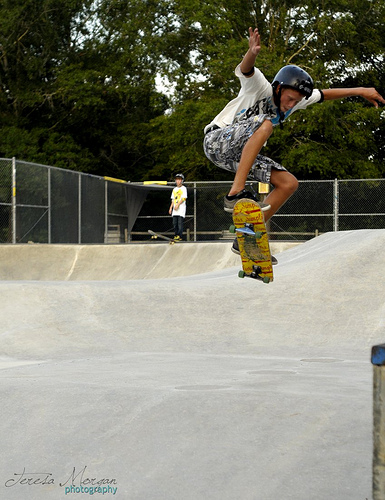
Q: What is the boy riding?
A: Skateboard.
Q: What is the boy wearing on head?
A: Helmet.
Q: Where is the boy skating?
A: Skate park.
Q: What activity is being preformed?
A: Skateboarding.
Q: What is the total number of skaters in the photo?
A: 2.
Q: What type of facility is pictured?
A: Skatepark.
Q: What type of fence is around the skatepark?
A: Chain link.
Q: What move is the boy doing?
A: Ollie.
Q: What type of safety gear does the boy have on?
A: A helmet.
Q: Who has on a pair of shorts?
A: The boy closest to the camera.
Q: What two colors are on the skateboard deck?
A: Red and yellow.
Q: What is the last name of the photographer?
A: Morgan.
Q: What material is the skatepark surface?
A: Concrete.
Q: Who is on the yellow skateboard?
A: A boy.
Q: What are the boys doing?
A: Skateboarding.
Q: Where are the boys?
A: At a skate park.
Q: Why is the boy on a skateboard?
A: He is skateboarding.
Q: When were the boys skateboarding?
A: During daylight hours.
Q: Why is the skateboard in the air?
A: The boy did a jump.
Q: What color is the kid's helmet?
A: Black.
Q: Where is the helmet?
A: On his head.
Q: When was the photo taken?
A: Daytime.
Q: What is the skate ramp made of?
A: Concrete.